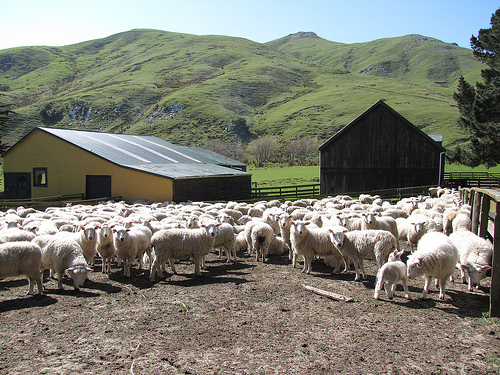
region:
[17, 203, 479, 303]
Herd of white sheep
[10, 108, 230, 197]
Yellow building with dark roof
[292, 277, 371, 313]
Piece of wood on the ground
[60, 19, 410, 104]
Rolling green hills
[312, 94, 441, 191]
Dark wooden barn with a sloping roof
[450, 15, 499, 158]
Dark green tree with thick branches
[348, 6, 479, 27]
Pale blue sky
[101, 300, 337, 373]
Rough brown dirt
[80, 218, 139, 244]
Three white sheep looking in the same direction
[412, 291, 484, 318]
Shadows on the ground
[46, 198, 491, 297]
There are many white animals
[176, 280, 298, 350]
The ground is dirt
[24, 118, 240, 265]
There is a barn in the back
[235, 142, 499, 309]
The fence is wooden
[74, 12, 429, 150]
The hills are in the back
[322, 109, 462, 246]
The barn is wooden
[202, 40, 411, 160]
The hills are green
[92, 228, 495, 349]
There are many sheep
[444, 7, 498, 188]
The tree is tall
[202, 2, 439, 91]
The sky is blue and clear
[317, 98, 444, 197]
Dark wood barn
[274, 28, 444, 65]
Green grassy mountain top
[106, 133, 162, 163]
metal roofing with sun reflection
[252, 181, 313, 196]
dark wood fencing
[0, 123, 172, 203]
Yellow house with metal roof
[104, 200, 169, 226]
Group of white sheep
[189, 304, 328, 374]
Dirt covered ground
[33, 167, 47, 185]
Small square window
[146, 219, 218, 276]
Fluffy haired white sheep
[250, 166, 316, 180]
Bright green grass covered field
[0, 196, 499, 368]
a flock of sheeps in a sheep pen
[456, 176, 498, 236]
pen has a wooden fence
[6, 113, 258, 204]
a building near the pen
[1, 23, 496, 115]
mountains are covered with green vegetation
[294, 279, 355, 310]
a wood stick on the sheep pen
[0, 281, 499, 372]
pen is cover with soil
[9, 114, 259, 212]
building is yellow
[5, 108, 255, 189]
building has black roof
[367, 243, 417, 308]
a lamb in middle of two adults sheeps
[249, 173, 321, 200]
a fence in middle of two homes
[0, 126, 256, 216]
a small yellow house.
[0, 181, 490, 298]
a herd of sheep near a small yellow house.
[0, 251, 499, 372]
a field of dirt.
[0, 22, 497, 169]
a lush green grass overed hills.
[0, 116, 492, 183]
a forest filled with green trees.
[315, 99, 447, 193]
a small brown house.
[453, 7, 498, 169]
a green leafy pine.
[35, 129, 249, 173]
a shiny roof on a farm.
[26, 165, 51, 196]
a window on the side of a building.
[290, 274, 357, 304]
a log on the ground.